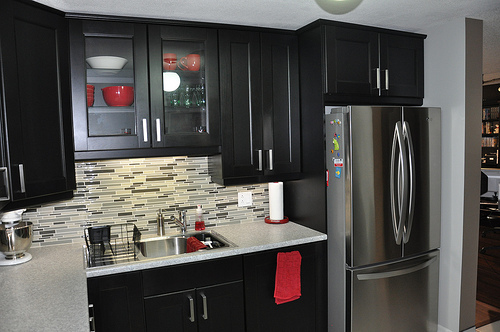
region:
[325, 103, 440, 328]
refrigerator with magnets on the side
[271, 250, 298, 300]
a red towel hanging below countertop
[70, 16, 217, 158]
black cabinet with glass inserts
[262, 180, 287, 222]
paper towels in a red holder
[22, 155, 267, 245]
brick wall behind the sink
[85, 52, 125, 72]
a white bowl on a glass shelf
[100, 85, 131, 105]
large red bowl on shelf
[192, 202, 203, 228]
a bottle of red liquid soap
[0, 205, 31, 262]
white mixer with stainless steel bowl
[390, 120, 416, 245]
door handles on the refrigerator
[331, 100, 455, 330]
a large stainless steel refrigerator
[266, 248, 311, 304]
a red hand towel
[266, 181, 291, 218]
a roll of paper towels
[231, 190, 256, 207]
a white light switch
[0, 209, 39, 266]
a mixer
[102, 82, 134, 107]
a large red bowl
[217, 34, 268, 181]
a black kitchen cabinet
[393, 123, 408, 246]
the door of a refrigerator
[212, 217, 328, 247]
a gray counter top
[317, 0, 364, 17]
part of a ceiling light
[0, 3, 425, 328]
Dark brown kitchen cabinets.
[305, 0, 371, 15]
A round white light fixture.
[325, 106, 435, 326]
A silver stainless steel refrigerator.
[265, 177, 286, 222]
Paper towels on a brown holder.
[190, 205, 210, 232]
A bottle of orange dish soap.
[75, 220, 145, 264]
A silver dish drainer.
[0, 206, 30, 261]
A silver bowl on a white mixer.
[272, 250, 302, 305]
A red towel hanging from the cupboard.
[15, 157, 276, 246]
A brick wall behind the sink.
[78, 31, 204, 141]
Red and white dishes behind the glass door.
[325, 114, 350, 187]
Magnets on the refrigerator side.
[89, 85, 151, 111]
Red bowls in the cabinet.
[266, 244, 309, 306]
Red towel hanging from the cabinet.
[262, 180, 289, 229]
Roll of paper towel under the cabinet.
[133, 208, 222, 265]
Sink with faucet on the counter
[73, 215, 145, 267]
A dish drainer on the side of the sink.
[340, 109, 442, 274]
Stainless steel refrigerator with two doors.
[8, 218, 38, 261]
A mixer on the cabinet.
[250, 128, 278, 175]
handles on the cabinet.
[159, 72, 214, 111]
Glasses in the cabinet.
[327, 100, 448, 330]
Stainless steel refrigerator in kitchen.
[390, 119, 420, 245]
Handles on stainless steel refrigerator.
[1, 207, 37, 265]
Mixer with aluminum bowl sitting on kitchen counter.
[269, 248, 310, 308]
Red dish towel hanging on door handle.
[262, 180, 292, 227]
White towel paper sitting on kitchen counter.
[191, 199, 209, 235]
Dish detergent sitting by kitchen sink.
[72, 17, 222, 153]
Dishes inside kitchen cabinet.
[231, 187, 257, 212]
Electrical outlet on kitchen wall.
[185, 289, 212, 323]
Two handles on kitchen cabinets.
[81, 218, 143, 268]
Dish drainer sitting in kitchen sink.